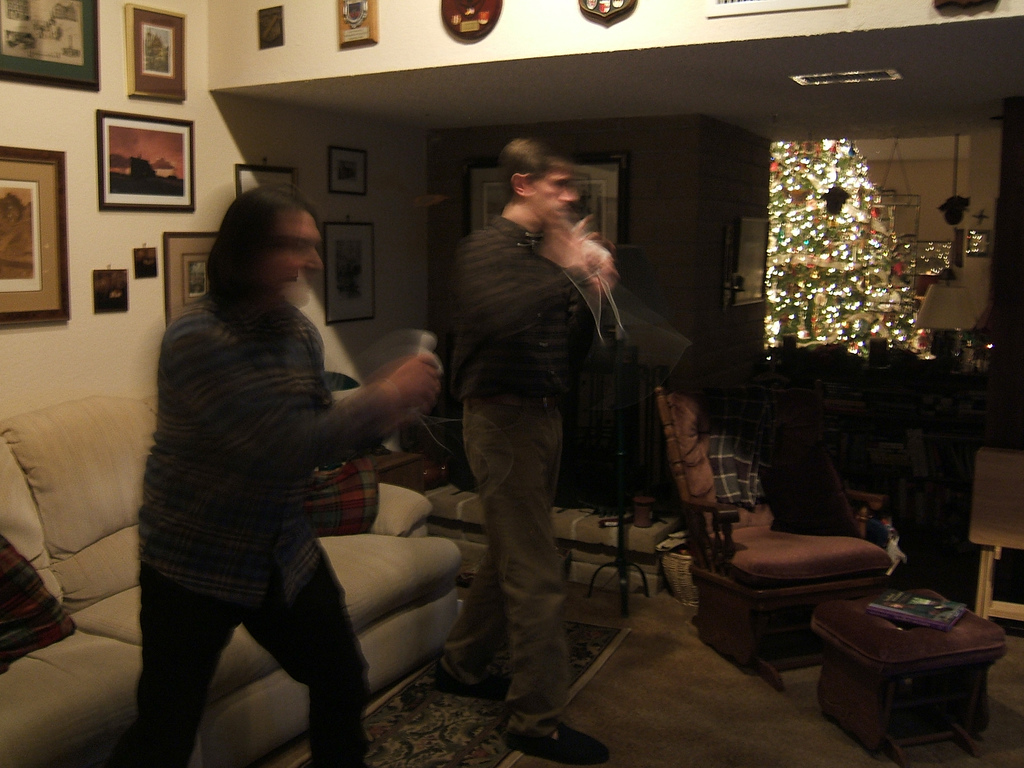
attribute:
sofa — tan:
[13, 358, 478, 763]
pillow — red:
[2, 524, 91, 680]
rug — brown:
[575, 620, 794, 765]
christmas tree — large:
[761, 114, 950, 370]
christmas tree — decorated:
[769, 125, 955, 370]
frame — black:
[91, 95, 206, 214]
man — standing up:
[106, 166, 456, 746]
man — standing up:
[423, 108, 612, 640]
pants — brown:
[442, 374, 631, 703]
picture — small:
[92, 104, 201, 217]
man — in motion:
[118, 180, 443, 762]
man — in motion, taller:
[427, 126, 624, 764]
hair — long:
[196, 182, 317, 347]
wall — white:
[37, 83, 70, 151]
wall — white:
[54, 126, 96, 179]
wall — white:
[76, 210, 115, 237]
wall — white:
[37, 98, 92, 151]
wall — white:
[37, 331, 128, 394]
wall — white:
[57, 335, 94, 377]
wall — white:
[31, 336, 96, 382]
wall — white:
[46, 305, 92, 390]